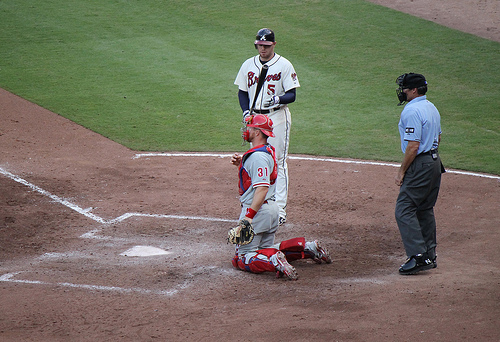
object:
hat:
[253, 28, 275, 46]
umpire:
[394, 71, 446, 275]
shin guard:
[231, 248, 279, 274]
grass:
[2, 6, 500, 169]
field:
[3, 4, 490, 340]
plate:
[120, 245, 172, 257]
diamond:
[119, 245, 172, 256]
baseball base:
[0, 212, 291, 296]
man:
[395, 72, 447, 276]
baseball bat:
[248, 64, 269, 114]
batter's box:
[0, 210, 292, 296]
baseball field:
[0, 3, 500, 342]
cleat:
[307, 239, 332, 263]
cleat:
[269, 251, 299, 281]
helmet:
[244, 114, 276, 138]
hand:
[234, 218, 256, 244]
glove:
[236, 218, 257, 243]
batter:
[234, 27, 301, 226]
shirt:
[234, 52, 302, 110]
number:
[267, 84, 275, 96]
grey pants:
[395, 148, 446, 260]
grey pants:
[234, 201, 309, 268]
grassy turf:
[0, 0, 497, 172]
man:
[227, 114, 332, 281]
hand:
[242, 109, 258, 122]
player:
[226, 114, 332, 281]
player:
[234, 27, 301, 225]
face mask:
[395, 73, 427, 106]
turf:
[2, 1, 500, 178]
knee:
[231, 250, 256, 272]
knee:
[259, 243, 270, 249]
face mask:
[239, 114, 252, 147]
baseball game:
[2, 1, 484, 338]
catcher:
[225, 115, 332, 282]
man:
[234, 27, 301, 226]